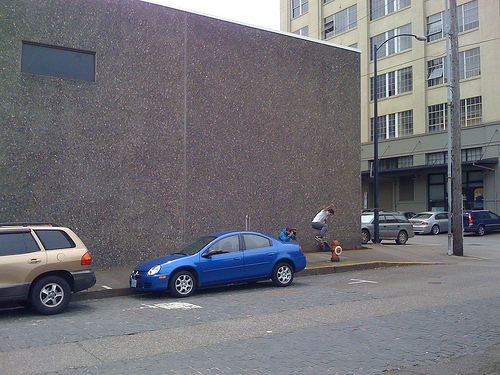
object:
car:
[130, 230, 306, 297]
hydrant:
[330, 238, 342, 262]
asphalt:
[355, 276, 432, 295]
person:
[310, 204, 335, 242]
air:
[316, 189, 339, 200]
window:
[369, 26, 412, 59]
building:
[281, 1, 500, 213]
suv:
[1, 222, 97, 314]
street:
[334, 268, 438, 299]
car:
[409, 210, 450, 234]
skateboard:
[316, 237, 331, 251]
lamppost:
[374, 33, 426, 242]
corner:
[362, 238, 454, 263]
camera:
[293, 229, 299, 234]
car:
[360, 209, 414, 245]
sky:
[201, 0, 290, 25]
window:
[369, 110, 411, 142]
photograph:
[292, 231, 301, 237]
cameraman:
[277, 226, 299, 244]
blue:
[280, 230, 287, 240]